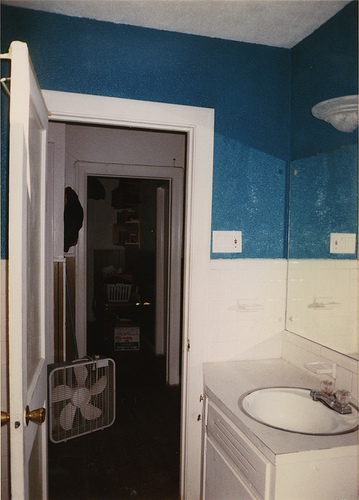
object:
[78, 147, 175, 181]
casing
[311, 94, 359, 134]
reflection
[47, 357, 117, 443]
fan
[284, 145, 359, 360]
mirror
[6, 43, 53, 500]
door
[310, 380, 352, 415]
faucet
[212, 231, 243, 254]
switch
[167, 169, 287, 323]
wall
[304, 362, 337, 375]
soap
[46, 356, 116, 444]
box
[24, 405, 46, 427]
handle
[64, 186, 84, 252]
garment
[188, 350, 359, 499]
cabinet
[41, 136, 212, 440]
doorway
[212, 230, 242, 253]
outlet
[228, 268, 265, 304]
tile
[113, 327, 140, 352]
basket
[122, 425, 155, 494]
floor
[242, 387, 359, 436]
plate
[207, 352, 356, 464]
top